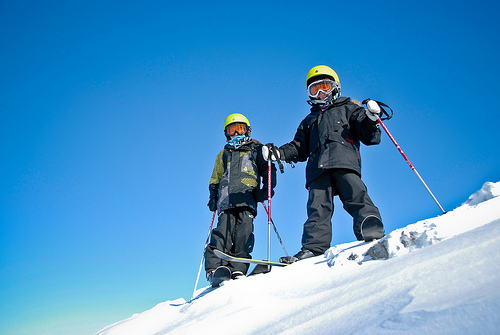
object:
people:
[204, 112, 276, 287]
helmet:
[224, 113, 253, 150]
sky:
[0, 11, 500, 335]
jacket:
[278, 97, 381, 186]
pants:
[301, 169, 382, 256]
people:
[262, 65, 384, 265]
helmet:
[306, 65, 342, 111]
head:
[303, 65, 341, 106]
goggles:
[224, 122, 252, 140]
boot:
[279, 248, 316, 263]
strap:
[362, 98, 394, 125]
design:
[373, 113, 446, 214]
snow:
[218, 236, 472, 320]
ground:
[89, 194, 484, 335]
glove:
[262, 146, 281, 162]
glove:
[365, 100, 381, 122]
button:
[320, 164, 323, 167]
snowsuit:
[278, 97, 381, 256]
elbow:
[289, 136, 309, 162]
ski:
[213, 249, 290, 267]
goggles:
[307, 79, 341, 97]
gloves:
[208, 183, 218, 210]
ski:
[360, 215, 384, 242]